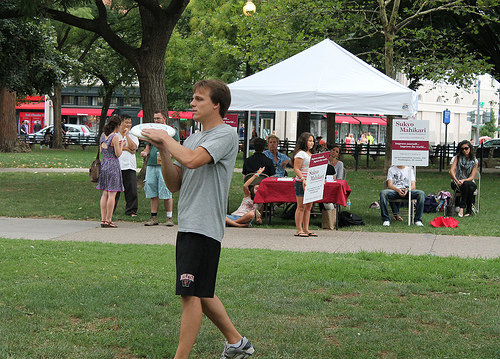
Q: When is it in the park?
A: Day time.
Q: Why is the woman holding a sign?
A: To advertise.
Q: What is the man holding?
A: Frisbee.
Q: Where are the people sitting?
A: Under the tent.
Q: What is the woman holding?
A: A sign.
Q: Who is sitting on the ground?
A: A woman with her hand raised.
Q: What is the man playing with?
A: A frisbee.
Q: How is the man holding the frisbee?
A: With 2 hands.